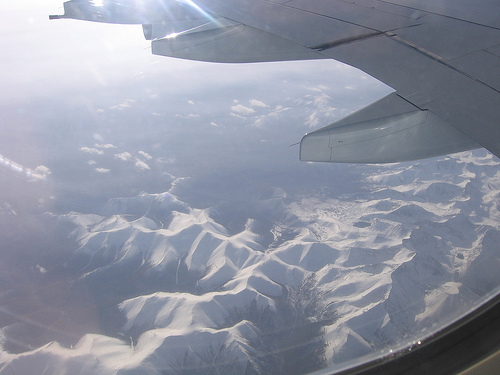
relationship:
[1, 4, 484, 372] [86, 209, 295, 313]
sky above mountain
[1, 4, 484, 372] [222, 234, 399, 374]
sky above mountain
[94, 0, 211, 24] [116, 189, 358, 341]
sun reflecting on ice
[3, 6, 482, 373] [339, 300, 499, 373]
window has strip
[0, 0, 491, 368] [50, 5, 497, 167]
airplane has wing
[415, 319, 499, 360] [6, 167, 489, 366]
strip inside window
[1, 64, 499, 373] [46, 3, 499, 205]
mountain below plane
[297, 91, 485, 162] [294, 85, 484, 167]
metal cover is on plane engine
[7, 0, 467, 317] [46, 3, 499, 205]
window is on plane